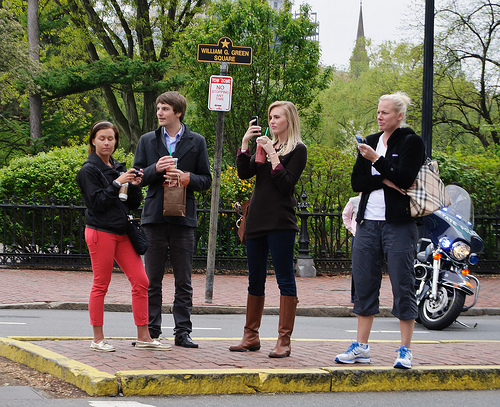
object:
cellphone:
[130, 166, 143, 180]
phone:
[246, 115, 259, 139]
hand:
[241, 118, 262, 141]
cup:
[254, 143, 266, 164]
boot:
[267, 294, 301, 359]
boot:
[228, 293, 267, 353]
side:
[117, 366, 500, 395]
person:
[228, 100, 309, 360]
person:
[334, 90, 427, 368]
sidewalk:
[0, 268, 500, 399]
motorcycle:
[413, 179, 484, 332]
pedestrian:
[74, 119, 176, 354]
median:
[0, 335, 500, 399]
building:
[348, 0, 372, 77]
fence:
[0, 187, 500, 272]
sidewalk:
[0, 266, 500, 318]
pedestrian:
[124, 90, 214, 350]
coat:
[133, 121, 213, 228]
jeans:
[83, 224, 151, 327]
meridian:
[1, 335, 500, 399]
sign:
[195, 36, 254, 66]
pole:
[203, 62, 233, 305]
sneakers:
[334, 342, 414, 370]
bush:
[227, 137, 353, 268]